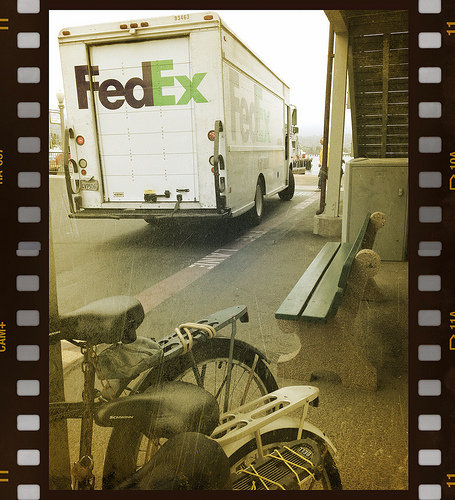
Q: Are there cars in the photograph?
A: No, there are no cars.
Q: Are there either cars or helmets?
A: No, there are no cars or helmets.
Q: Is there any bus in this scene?
A: No, there are no buses.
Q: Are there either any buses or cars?
A: No, there are no buses or cars.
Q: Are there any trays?
A: No, there are no trays.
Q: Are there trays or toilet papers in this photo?
A: No, there are no trays or toilet papers.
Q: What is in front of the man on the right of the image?
A: The pole is in front of the man.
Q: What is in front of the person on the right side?
A: The pole is in front of the man.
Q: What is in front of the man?
A: The pole is in front of the man.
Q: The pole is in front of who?
A: The pole is in front of the man.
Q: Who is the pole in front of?
A: The pole is in front of the man.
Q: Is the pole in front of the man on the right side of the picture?
A: Yes, the pole is in front of the man.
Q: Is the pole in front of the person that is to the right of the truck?
A: Yes, the pole is in front of the man.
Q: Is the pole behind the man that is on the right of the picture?
A: No, the pole is in front of the man.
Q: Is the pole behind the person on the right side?
A: No, the pole is in front of the man.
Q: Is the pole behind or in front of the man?
A: The pole is in front of the man.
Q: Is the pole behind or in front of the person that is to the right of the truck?
A: The pole is in front of the man.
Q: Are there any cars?
A: No, there are no cars.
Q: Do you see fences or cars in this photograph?
A: No, there are no cars or fences.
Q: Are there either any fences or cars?
A: No, there are no cars or fences.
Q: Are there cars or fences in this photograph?
A: No, there are no cars or fences.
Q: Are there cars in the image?
A: No, there are no cars.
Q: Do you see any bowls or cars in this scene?
A: No, there are no cars or bowls.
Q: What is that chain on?
A: The chain is on the bike.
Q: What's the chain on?
A: The chain is on the bike.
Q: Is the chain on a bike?
A: Yes, the chain is on a bike.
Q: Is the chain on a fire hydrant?
A: No, the chain is on a bike.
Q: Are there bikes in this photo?
A: Yes, there is a bike.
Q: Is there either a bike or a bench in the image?
A: Yes, there is a bike.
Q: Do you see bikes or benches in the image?
A: Yes, there is a bike.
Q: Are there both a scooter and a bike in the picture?
A: No, there is a bike but no scooters.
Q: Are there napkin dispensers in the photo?
A: No, there are no napkin dispensers.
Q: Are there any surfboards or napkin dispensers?
A: No, there are no napkin dispensers or surfboards.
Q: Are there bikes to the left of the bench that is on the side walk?
A: Yes, there is a bike to the left of the bench.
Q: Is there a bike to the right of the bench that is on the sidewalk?
A: No, the bike is to the left of the bench.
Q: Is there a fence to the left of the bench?
A: No, there is a bike to the left of the bench.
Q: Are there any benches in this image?
A: Yes, there is a bench.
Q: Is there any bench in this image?
A: Yes, there is a bench.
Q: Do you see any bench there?
A: Yes, there is a bench.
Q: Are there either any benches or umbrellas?
A: Yes, there is a bench.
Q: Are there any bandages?
A: No, there are no bandages.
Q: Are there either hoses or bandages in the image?
A: No, there are no bandages or hoses.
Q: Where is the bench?
A: The bench is on the sidewalk.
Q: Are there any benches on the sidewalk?
A: Yes, there is a bench on the sidewalk.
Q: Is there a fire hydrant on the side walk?
A: No, there is a bench on the side walk.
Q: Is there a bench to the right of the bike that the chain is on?
A: Yes, there is a bench to the right of the bike.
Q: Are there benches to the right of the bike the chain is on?
A: Yes, there is a bench to the right of the bike.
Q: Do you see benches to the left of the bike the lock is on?
A: No, the bench is to the right of the bike.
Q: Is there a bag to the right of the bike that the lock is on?
A: No, there is a bench to the right of the bike.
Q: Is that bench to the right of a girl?
A: No, the bench is to the right of a bike.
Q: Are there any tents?
A: No, there are no tents.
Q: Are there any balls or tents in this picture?
A: No, there are no tents or balls.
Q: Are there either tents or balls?
A: No, there are no tents or balls.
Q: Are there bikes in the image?
A: Yes, there are bikes.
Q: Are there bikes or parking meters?
A: Yes, there are bikes.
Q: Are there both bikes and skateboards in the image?
A: No, there are bikes but no skateboards.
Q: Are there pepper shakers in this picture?
A: No, there are no pepper shakers.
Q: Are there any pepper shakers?
A: No, there are no pepper shakers.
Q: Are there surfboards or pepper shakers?
A: No, there are no pepper shakers or surfboards.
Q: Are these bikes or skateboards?
A: These are bikes.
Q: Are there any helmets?
A: No, there are no helmets.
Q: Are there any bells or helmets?
A: No, there are no helmets or bells.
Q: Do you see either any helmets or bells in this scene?
A: No, there are no helmets or bells.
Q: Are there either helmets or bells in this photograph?
A: No, there are no helmets or bells.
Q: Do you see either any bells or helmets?
A: No, there are no helmets or bells.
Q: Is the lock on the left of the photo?
A: Yes, the lock is on the left of the image.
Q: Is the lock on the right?
A: No, the lock is on the left of the image.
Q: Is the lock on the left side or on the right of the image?
A: The lock is on the left of the image.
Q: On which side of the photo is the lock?
A: The lock is on the left of the image.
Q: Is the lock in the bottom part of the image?
A: Yes, the lock is in the bottom of the image.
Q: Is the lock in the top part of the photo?
A: No, the lock is in the bottom of the image.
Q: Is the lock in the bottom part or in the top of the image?
A: The lock is in the bottom of the image.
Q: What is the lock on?
A: The lock is on the bike.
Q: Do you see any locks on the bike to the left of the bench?
A: Yes, there is a lock on the bike.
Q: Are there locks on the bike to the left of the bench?
A: Yes, there is a lock on the bike.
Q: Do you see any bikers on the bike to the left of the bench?
A: No, there is a lock on the bike.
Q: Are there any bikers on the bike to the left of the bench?
A: No, there is a lock on the bike.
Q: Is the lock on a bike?
A: Yes, the lock is on a bike.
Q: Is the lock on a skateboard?
A: No, the lock is on a bike.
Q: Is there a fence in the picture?
A: No, there are no fences.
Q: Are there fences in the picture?
A: No, there are no fences.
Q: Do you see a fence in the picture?
A: No, there are no fences.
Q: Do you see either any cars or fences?
A: No, there are no fences or cars.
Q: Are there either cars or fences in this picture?
A: No, there are no fences or cars.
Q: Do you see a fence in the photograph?
A: No, there are no fences.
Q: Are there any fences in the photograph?
A: No, there are no fences.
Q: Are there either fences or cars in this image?
A: No, there are no fences or cars.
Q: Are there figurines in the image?
A: No, there are no figurines.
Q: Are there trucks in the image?
A: Yes, there is a truck.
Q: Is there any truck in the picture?
A: Yes, there is a truck.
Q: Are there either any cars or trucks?
A: Yes, there is a truck.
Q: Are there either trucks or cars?
A: Yes, there is a truck.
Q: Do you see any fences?
A: No, there are no fences.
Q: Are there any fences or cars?
A: No, there are no fences or cars.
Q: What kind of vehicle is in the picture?
A: The vehicle is a truck.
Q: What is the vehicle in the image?
A: The vehicle is a truck.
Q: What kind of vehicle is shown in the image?
A: The vehicle is a truck.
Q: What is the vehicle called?
A: The vehicle is a truck.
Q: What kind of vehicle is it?
A: The vehicle is a truck.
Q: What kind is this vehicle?
A: This is a truck.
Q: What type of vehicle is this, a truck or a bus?
A: This is a truck.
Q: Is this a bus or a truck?
A: This is a truck.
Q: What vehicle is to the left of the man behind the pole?
A: The vehicle is a truck.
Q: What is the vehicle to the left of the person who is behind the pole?
A: The vehicle is a truck.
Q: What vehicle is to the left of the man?
A: The vehicle is a truck.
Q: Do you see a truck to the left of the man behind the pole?
A: Yes, there is a truck to the left of the man.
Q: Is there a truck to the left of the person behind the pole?
A: Yes, there is a truck to the left of the man.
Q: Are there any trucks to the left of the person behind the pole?
A: Yes, there is a truck to the left of the man.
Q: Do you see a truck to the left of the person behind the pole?
A: Yes, there is a truck to the left of the man.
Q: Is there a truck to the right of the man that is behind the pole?
A: No, the truck is to the left of the man.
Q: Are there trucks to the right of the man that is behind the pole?
A: No, the truck is to the left of the man.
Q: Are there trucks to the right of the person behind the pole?
A: No, the truck is to the left of the man.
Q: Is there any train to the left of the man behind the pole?
A: No, there is a truck to the left of the man.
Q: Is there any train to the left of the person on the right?
A: No, there is a truck to the left of the man.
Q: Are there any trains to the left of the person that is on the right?
A: No, there is a truck to the left of the man.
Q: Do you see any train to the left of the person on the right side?
A: No, there is a truck to the left of the man.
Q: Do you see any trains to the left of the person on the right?
A: No, there is a truck to the left of the man.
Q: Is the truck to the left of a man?
A: Yes, the truck is to the left of a man.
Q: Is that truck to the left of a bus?
A: No, the truck is to the left of a man.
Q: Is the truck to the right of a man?
A: No, the truck is to the left of a man.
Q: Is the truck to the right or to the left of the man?
A: The truck is to the left of the man.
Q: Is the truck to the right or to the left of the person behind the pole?
A: The truck is to the left of the man.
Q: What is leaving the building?
A: The truck is leaving the building.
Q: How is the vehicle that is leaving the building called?
A: The vehicle is a truck.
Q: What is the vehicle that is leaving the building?
A: The vehicle is a truck.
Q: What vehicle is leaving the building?
A: The vehicle is a truck.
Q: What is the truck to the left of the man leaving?
A: The truck is leaving the building.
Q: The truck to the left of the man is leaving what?
A: The truck is leaving the building.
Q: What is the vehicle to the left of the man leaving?
A: The truck is leaving the building.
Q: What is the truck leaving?
A: The truck is leaving the building.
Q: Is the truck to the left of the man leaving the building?
A: Yes, the truck is leaving the building.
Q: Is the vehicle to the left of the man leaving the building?
A: Yes, the truck is leaving the building.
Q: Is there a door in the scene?
A: Yes, there is a door.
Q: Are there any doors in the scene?
A: Yes, there is a door.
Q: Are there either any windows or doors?
A: Yes, there is a door.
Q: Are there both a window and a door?
A: No, there is a door but no windows.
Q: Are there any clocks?
A: No, there are no clocks.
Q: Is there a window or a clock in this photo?
A: No, there are no clocks or windows.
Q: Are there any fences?
A: No, there are no fences.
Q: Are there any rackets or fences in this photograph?
A: No, there are no fences or rackets.